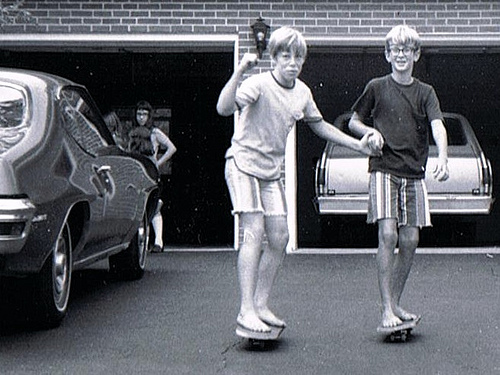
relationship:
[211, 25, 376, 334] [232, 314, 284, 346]
boy riding skateboard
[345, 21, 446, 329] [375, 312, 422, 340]
boy riding skateboard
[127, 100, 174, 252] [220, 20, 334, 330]
girl watching boys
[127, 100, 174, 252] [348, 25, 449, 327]
girl watching boy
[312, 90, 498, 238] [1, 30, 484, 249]
car parked in garage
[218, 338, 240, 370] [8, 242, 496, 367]
crack formed in ground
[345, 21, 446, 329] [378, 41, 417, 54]
boy wearing eyeglasses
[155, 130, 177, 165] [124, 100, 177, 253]
arm belonging to girl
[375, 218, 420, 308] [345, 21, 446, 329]
leg of a boy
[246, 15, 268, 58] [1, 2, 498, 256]
fixture on house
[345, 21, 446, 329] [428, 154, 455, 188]
boy holding hand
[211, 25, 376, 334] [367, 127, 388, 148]
boy holding hand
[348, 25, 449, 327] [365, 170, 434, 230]
boy have shorts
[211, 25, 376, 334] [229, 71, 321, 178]
boy has white shirt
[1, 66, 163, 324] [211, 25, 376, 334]
car next to boy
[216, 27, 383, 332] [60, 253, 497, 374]
boy are on sidewalk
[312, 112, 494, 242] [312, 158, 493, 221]
car has back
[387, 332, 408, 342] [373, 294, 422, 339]
wheels under skateboard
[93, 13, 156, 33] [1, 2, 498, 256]
bricks in house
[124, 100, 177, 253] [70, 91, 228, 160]
girl on background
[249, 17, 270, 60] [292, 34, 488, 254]
fixture on garage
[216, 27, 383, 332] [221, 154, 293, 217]
boy wears shorts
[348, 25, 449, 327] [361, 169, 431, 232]
boy wears shorts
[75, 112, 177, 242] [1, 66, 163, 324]
door handle on car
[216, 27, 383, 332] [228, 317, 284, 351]
boy on skateboard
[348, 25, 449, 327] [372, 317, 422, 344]
boy on skateboard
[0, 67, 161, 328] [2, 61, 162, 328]
car has tires